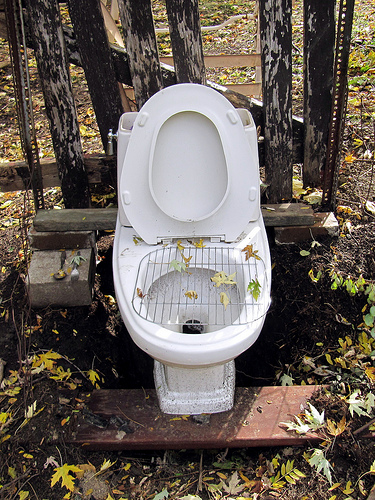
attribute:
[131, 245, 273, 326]
grill grate — silver, metal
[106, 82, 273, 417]
toilet — white, open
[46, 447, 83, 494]
leaf — yellow, golden, beautiful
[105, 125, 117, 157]
handle — shiny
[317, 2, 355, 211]
rod — rusted, metal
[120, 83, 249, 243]
seat — up, raised, white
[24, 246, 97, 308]
block — gray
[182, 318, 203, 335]
hole — drain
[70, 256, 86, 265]
leaf — green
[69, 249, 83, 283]
fork — silver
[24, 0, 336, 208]
trunks — brown, white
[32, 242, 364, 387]
dirt — brown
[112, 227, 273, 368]
bowl — white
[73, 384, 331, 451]
board — wooden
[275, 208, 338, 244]
brick — red